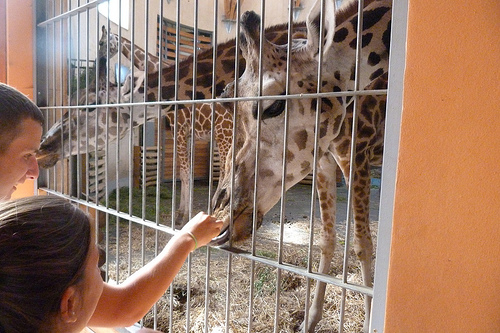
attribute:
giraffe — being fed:
[36, 20, 306, 168]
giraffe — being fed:
[93, 26, 233, 224]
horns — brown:
[219, 9, 339, 90]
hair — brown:
[6, 77, 33, 124]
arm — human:
[45, 177, 296, 317]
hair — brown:
[4, 176, 98, 318]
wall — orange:
[387, 4, 499, 331]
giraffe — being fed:
[212, 1, 392, 331]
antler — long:
[234, 0, 276, 57]